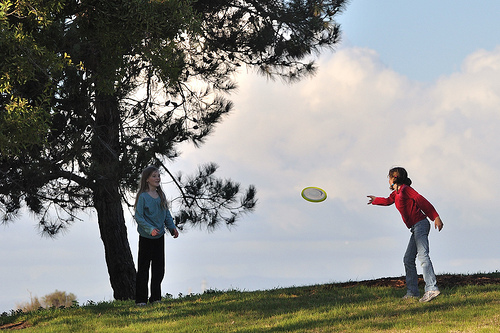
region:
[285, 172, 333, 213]
Frisbee that is being thrown.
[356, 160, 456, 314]
Girl who threw the Frisbee.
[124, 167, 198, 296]
Girl going to catch the Frisbee.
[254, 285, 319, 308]
Shadow being cast by the tree.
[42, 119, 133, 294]
Tree the girl is standing under.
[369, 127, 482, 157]
Clouds in the sky.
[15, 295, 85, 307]
Dry grass on the hill.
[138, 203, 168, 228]
Blue shirt of the girl.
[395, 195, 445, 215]
Red shirt of the girl.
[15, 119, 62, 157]
Green leaves on the tree.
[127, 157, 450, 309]
Two girls playing frisbee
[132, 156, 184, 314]
Girl wearing a blue shirt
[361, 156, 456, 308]
Girl wearing a red shirt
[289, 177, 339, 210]
Frisbee flying through the air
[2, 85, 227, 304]
Girl standing next to large tree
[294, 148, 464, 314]
Girl throwing frisbee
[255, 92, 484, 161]
White clouds in the sky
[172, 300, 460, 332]
Green grass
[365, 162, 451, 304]
Girl with brown hair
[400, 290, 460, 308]
White tennis shoes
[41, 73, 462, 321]
Two young people throwing a frisbee.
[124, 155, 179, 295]
A girl with long hair.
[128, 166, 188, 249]
A girl in a long sleeve shirt.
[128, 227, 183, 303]
A pair of dark pants.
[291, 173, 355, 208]
A frisbee being thrown through the air.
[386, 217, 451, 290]
A pair of light colored pants.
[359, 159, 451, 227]
A red long sleeve shirt.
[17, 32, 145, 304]
A tall green tree.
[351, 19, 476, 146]
The sky is blue with white clouds.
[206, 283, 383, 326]
The green grass in a field.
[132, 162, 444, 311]
two girls playing frisbee outside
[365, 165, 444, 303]
girl wearing a red shirt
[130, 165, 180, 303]
girl wearing a blue shirt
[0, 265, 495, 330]
green grass on a hillside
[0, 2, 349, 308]
girl under a tree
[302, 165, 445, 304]
girl playing frisbee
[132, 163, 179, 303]
girl with long hair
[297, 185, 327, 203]
white frisbee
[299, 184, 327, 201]
white frisbee flying through the air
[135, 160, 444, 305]
girls playing outside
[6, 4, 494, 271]
blue sky with white clouds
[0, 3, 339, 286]
tall green pine tree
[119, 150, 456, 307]
two girls playing frisbee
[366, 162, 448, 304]
girl with brown hair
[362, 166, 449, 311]
girl wearing blue jeans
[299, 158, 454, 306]
girl throwing the frisbee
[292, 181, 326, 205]
round white frisbee midair